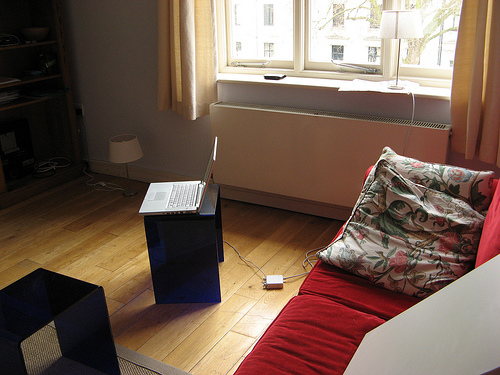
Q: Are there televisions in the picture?
A: No, there are no televisions.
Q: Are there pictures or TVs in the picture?
A: No, there are no TVs or pictures.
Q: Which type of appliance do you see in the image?
A: The appliance is a radiator.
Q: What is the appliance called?
A: The appliance is a radiator.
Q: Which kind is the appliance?
A: The appliance is a radiator.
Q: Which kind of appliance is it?
A: The appliance is a radiator.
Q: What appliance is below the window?
A: The appliance is a radiator.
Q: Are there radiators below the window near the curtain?
A: Yes, there is a radiator below the window.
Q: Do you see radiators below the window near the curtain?
A: Yes, there is a radiator below the window.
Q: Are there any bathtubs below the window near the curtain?
A: No, there is a radiator below the window.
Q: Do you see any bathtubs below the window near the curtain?
A: No, there is a radiator below the window.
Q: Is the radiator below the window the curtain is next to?
A: Yes, the radiator is below the window.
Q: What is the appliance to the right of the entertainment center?
A: The appliance is a radiator.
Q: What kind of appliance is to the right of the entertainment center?
A: The appliance is a radiator.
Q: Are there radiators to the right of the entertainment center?
A: Yes, there is a radiator to the right of the entertainment center.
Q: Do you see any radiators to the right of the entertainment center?
A: Yes, there is a radiator to the right of the entertainment center.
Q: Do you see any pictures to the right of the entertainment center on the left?
A: No, there is a radiator to the right of the entertainment center.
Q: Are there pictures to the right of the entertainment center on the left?
A: No, there is a radiator to the right of the entertainment center.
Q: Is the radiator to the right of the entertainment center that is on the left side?
A: Yes, the radiator is to the right of the entertainment center.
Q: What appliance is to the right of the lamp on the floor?
A: The appliance is a radiator.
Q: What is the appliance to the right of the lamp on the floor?
A: The appliance is a radiator.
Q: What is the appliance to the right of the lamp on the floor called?
A: The appliance is a radiator.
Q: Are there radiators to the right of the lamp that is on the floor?
A: Yes, there is a radiator to the right of the lamp.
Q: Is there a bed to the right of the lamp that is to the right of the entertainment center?
A: No, there is a radiator to the right of the lamp.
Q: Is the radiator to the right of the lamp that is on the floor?
A: Yes, the radiator is to the right of the lamp.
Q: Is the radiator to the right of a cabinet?
A: No, the radiator is to the right of the lamp.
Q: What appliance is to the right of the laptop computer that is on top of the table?
A: The appliance is a radiator.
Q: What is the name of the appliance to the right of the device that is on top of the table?
A: The appliance is a radiator.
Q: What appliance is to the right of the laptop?
A: The appliance is a radiator.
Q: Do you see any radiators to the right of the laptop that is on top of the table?
A: Yes, there is a radiator to the right of the laptop.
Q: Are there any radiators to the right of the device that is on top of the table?
A: Yes, there is a radiator to the right of the laptop.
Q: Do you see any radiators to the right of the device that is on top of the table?
A: Yes, there is a radiator to the right of the laptop.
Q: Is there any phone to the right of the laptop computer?
A: No, there is a radiator to the right of the laptop computer.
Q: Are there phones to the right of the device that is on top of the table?
A: No, there is a radiator to the right of the laptop computer.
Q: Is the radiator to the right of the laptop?
A: Yes, the radiator is to the right of the laptop.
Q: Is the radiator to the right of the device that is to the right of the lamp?
A: Yes, the radiator is to the right of the laptop.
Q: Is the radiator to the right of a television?
A: No, the radiator is to the right of the laptop.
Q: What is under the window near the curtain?
A: The radiator is under the window.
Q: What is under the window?
A: The radiator is under the window.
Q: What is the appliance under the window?
A: The appliance is a radiator.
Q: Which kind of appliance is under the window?
A: The appliance is a radiator.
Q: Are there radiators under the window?
A: Yes, there is a radiator under the window.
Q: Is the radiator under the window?
A: Yes, the radiator is under the window.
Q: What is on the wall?
A: The radiator is on the wall.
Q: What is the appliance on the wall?
A: The appliance is a radiator.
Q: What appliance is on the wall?
A: The appliance is a radiator.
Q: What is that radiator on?
A: The radiator is on the wall.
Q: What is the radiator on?
A: The radiator is on the wall.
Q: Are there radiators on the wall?
A: Yes, there is a radiator on the wall.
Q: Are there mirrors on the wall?
A: No, there is a radiator on the wall.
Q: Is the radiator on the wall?
A: Yes, the radiator is on the wall.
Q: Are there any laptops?
A: Yes, there is a laptop.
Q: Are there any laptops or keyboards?
A: Yes, there is a laptop.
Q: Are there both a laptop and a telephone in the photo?
A: No, there is a laptop but no phones.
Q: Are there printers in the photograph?
A: No, there are no printers.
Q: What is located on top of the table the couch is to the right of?
A: The laptop is on top of the table.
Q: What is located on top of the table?
A: The laptop is on top of the table.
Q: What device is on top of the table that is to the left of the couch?
A: The device is a laptop.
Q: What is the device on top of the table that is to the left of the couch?
A: The device is a laptop.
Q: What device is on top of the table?
A: The device is a laptop.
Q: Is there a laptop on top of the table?
A: Yes, there is a laptop on top of the table.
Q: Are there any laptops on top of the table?
A: Yes, there is a laptop on top of the table.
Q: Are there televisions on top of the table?
A: No, there is a laptop on top of the table.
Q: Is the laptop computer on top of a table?
A: Yes, the laptop computer is on top of a table.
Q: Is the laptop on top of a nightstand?
A: No, the laptop is on top of a table.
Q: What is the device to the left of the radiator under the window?
A: The device is a laptop.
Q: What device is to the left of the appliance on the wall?
A: The device is a laptop.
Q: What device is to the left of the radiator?
A: The device is a laptop.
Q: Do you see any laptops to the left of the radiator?
A: Yes, there is a laptop to the left of the radiator.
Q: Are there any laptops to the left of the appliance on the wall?
A: Yes, there is a laptop to the left of the radiator.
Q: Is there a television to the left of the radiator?
A: No, there is a laptop to the left of the radiator.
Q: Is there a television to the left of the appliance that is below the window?
A: No, there is a laptop to the left of the radiator.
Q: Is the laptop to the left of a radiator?
A: Yes, the laptop is to the left of a radiator.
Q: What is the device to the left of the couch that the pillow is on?
A: The device is a laptop.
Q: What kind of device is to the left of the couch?
A: The device is a laptop.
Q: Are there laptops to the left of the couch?
A: Yes, there is a laptop to the left of the couch.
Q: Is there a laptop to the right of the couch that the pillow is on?
A: No, the laptop is to the left of the couch.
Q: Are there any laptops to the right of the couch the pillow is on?
A: No, the laptop is to the left of the couch.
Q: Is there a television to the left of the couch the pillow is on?
A: No, there is a laptop to the left of the couch.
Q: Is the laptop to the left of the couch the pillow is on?
A: Yes, the laptop is to the left of the couch.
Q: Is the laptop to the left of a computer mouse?
A: No, the laptop is to the left of the couch.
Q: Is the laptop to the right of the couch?
A: No, the laptop is to the left of the couch.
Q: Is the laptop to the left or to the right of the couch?
A: The laptop is to the left of the couch.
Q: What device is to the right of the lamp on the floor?
A: The device is a laptop.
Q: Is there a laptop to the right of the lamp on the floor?
A: Yes, there is a laptop to the right of the lamp.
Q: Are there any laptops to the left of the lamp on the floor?
A: No, the laptop is to the right of the lamp.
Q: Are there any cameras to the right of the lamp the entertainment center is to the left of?
A: No, there is a laptop to the right of the lamp.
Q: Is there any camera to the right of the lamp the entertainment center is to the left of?
A: No, there is a laptop to the right of the lamp.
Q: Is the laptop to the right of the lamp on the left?
A: Yes, the laptop is to the right of the lamp.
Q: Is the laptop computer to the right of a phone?
A: No, the laptop computer is to the right of the lamp.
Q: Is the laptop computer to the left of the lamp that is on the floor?
A: No, the laptop computer is to the right of the lamp.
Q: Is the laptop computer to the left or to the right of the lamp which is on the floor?
A: The laptop computer is to the right of the lamp.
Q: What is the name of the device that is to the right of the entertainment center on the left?
A: The device is a laptop.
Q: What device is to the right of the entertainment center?
A: The device is a laptop.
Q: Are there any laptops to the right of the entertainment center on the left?
A: Yes, there is a laptop to the right of the entertainment center.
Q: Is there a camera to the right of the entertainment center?
A: No, there is a laptop to the right of the entertainment center.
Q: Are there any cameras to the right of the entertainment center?
A: No, there is a laptop to the right of the entertainment center.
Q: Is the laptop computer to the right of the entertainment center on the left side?
A: Yes, the laptop computer is to the right of the entertainment center.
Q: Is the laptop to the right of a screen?
A: No, the laptop is to the right of the entertainment center.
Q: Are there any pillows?
A: Yes, there is a pillow.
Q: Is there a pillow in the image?
A: Yes, there is a pillow.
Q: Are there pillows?
A: Yes, there is a pillow.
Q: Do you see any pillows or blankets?
A: Yes, there is a pillow.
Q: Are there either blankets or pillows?
A: Yes, there is a pillow.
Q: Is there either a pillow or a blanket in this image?
A: Yes, there is a pillow.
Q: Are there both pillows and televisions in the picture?
A: No, there is a pillow but no televisions.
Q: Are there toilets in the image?
A: No, there are no toilets.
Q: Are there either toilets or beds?
A: No, there are no toilets or beds.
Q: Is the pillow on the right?
A: Yes, the pillow is on the right of the image.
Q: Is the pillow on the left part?
A: No, the pillow is on the right of the image.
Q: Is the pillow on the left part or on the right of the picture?
A: The pillow is on the right of the image.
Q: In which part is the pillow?
A: The pillow is on the right of the image.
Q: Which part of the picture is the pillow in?
A: The pillow is on the right of the image.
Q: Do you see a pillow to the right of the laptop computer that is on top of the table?
A: Yes, there is a pillow to the right of the laptop computer.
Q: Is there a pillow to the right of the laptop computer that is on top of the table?
A: Yes, there is a pillow to the right of the laptop computer.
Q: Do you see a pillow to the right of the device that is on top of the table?
A: Yes, there is a pillow to the right of the laptop computer.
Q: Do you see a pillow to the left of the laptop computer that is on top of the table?
A: No, the pillow is to the right of the laptop.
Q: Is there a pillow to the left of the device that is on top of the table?
A: No, the pillow is to the right of the laptop.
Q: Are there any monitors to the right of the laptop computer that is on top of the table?
A: No, there is a pillow to the right of the laptop.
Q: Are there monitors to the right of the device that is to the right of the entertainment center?
A: No, there is a pillow to the right of the laptop.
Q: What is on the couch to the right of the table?
A: The pillow is on the couch.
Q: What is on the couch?
A: The pillow is on the couch.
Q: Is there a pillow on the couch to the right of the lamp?
A: Yes, there is a pillow on the couch.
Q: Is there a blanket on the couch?
A: No, there is a pillow on the couch.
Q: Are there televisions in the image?
A: No, there are no televisions.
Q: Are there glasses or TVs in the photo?
A: No, there are no TVs or glasses.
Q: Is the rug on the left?
A: Yes, the rug is on the left of the image.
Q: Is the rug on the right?
A: No, the rug is on the left of the image.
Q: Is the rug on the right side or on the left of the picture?
A: The rug is on the left of the image.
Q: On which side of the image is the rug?
A: The rug is on the left of the image.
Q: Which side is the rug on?
A: The rug is on the left of the image.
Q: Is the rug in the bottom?
A: Yes, the rug is in the bottom of the image.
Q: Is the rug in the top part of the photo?
A: No, the rug is in the bottom of the image.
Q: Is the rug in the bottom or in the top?
A: The rug is in the bottom of the image.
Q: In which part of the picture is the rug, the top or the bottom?
A: The rug is in the bottom of the image.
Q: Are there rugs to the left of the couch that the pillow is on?
A: Yes, there is a rug to the left of the couch.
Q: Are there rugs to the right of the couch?
A: No, the rug is to the left of the couch.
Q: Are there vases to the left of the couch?
A: No, there is a rug to the left of the couch.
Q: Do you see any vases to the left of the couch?
A: No, there is a rug to the left of the couch.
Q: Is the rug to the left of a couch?
A: Yes, the rug is to the left of a couch.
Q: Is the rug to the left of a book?
A: No, the rug is to the left of a couch.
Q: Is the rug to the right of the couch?
A: No, the rug is to the left of the couch.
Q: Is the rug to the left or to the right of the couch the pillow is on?
A: The rug is to the left of the couch.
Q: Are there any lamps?
A: Yes, there is a lamp.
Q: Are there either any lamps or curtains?
A: Yes, there is a lamp.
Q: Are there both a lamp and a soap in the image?
A: No, there is a lamp but no soaps.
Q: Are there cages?
A: No, there are no cages.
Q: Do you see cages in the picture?
A: No, there are no cages.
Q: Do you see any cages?
A: No, there are no cages.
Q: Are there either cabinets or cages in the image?
A: No, there are no cages or cabinets.